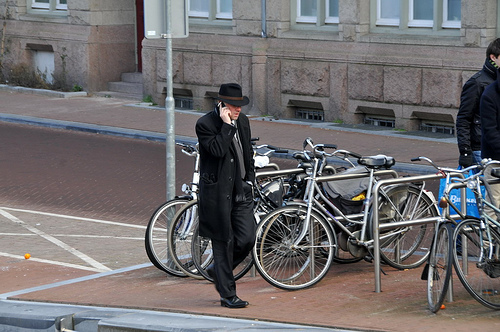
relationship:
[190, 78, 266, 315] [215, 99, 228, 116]
man on phone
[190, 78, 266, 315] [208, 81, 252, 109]
man has hat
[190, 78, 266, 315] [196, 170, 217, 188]
man has gloves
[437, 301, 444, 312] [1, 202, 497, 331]
orange on floor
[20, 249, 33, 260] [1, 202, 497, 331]
orange on floor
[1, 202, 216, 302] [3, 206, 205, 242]
road has stripes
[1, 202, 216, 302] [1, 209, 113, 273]
road has stripes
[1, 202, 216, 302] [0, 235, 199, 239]
road has stripes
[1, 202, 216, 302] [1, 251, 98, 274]
road has stripes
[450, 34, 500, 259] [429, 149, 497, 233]
man carrying bag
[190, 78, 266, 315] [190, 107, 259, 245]
man wearing coat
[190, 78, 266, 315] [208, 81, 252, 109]
man wearing hat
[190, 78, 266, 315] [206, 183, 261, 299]
man wearing pants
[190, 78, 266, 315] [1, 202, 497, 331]
man on floor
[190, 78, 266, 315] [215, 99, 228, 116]
man holding phone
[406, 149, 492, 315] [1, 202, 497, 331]
bicycles on floor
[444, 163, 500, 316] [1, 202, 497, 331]
bicycles on floor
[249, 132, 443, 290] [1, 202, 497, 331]
bicycles on floor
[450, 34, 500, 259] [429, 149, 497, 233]
man holding bag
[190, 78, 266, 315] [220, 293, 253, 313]
man has shoe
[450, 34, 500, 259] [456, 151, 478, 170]
man wearing gloves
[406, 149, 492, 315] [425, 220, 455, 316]
bicycles with wheel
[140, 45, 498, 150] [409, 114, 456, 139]
basement has windows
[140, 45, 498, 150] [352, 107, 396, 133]
basement has windows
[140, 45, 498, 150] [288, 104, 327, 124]
basement has windows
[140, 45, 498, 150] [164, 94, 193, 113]
basement has windows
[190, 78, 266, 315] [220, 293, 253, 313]
man wearing shoe